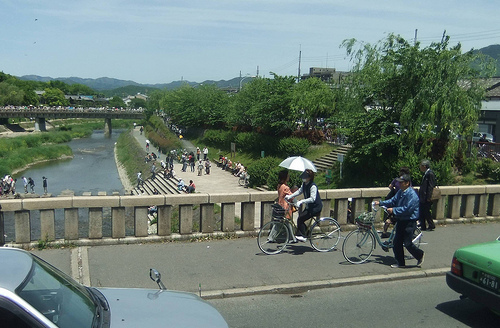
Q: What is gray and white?
A: An umbrella.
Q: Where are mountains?
A: Far in the distance.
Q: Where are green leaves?
A: On trees.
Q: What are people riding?
A: Bicycles.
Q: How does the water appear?
A: Calm.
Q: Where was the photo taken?
A: On a bridge.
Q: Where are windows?
A: On gray car.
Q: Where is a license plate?
A: On back of the green car.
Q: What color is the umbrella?
A: Grey and white.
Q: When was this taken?
A: Daytime.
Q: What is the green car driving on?
A: A bridge.